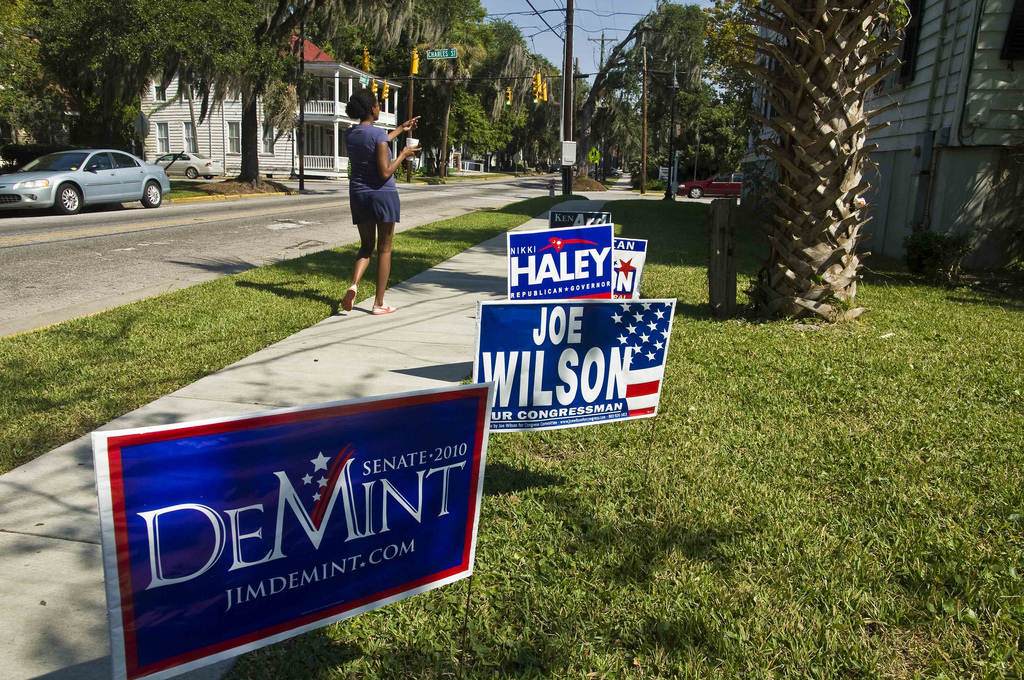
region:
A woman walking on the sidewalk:
[334, 79, 417, 323]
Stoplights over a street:
[482, 63, 555, 112]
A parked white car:
[155, 149, 225, 181]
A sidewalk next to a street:
[2, 183, 736, 668]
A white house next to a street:
[140, 23, 401, 183]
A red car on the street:
[664, 165, 744, 198]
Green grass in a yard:
[220, 199, 1021, 671]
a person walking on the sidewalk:
[338, 95, 395, 304]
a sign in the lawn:
[104, 430, 487, 652]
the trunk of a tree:
[771, 47, 871, 305]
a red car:
[683, 176, 737, 197]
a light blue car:
[18, 152, 158, 198]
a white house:
[147, 51, 386, 159]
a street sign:
[413, 42, 472, 58]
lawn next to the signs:
[669, 351, 1003, 636]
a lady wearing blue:
[343, 88, 395, 273]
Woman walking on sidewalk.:
[340, 85, 411, 321]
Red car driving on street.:
[668, 165, 742, 201]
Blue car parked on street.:
[5, 142, 170, 213]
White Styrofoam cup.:
[400, 136, 423, 165]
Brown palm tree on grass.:
[747, 7, 890, 322]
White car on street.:
[147, 146, 227, 178]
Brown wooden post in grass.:
[705, 196, 745, 313]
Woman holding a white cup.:
[342, 86, 412, 312]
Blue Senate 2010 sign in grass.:
[100, 408, 497, 650]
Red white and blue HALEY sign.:
[506, 220, 615, 301]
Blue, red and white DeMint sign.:
[89, 381, 495, 675]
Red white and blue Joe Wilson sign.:
[477, 295, 677, 438]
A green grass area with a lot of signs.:
[235, 200, 1022, 678]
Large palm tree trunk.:
[738, 4, 895, 321]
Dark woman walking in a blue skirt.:
[340, 93, 423, 312]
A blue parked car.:
[3, 147, 168, 212]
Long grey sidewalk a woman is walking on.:
[0, 195, 617, 677]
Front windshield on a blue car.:
[17, 152, 87, 171]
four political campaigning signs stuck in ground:
[81, 212, 686, 675]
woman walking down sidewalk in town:
[328, 85, 430, 314]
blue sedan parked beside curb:
[2, 145, 177, 218]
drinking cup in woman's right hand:
[398, 131, 425, 169]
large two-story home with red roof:
[135, 16, 411, 184]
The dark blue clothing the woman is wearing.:
[343, 129, 404, 221]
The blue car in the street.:
[8, 141, 165, 215]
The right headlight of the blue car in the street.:
[5, 165, 47, 188]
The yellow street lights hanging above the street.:
[333, 41, 565, 127]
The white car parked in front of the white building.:
[157, 145, 218, 171]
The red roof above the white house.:
[281, 41, 351, 61]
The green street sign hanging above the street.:
[407, 46, 465, 57]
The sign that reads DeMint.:
[100, 386, 487, 666]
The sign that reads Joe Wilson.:
[477, 287, 675, 436]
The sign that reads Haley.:
[508, 224, 622, 298]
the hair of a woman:
[342, 92, 380, 121]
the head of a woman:
[336, 92, 400, 135]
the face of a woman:
[374, 107, 388, 124]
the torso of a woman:
[345, 119, 388, 180]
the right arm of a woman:
[371, 142, 432, 185]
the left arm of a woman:
[365, 104, 420, 147]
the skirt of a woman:
[333, 177, 400, 226]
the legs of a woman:
[342, 215, 403, 305]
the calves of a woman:
[336, 247, 409, 299]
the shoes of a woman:
[333, 282, 409, 325]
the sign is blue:
[81, 375, 494, 674]